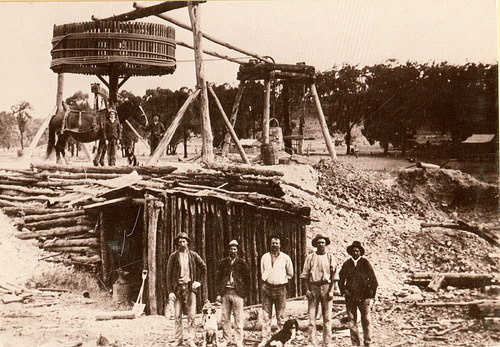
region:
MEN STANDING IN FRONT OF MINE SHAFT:
[158, 220, 390, 345]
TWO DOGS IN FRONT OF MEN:
[191, 304, 317, 342]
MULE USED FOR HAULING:
[47, 94, 154, 162]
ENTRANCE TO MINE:
[78, 170, 326, 314]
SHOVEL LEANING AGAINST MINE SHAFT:
[126, 265, 163, 319]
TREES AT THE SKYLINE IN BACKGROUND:
[140, 59, 493, 156]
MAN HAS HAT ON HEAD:
[165, 228, 204, 257]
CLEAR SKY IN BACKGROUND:
[6, 0, 492, 78]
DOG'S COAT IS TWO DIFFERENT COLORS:
[265, 313, 311, 345]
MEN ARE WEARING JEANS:
[163, 281, 389, 344]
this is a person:
[338, 240, 386, 341]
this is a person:
[295, 223, 354, 342]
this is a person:
[256, 231, 301, 333]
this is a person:
[206, 216, 251, 344]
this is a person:
[146, 227, 206, 344]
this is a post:
[190, 7, 217, 163]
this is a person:
[136, 107, 176, 158]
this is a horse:
[29, 90, 151, 191]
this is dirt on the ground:
[401, 273, 491, 327]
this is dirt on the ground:
[306, 182, 406, 237]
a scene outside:
[9, 6, 491, 344]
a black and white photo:
[6, 5, 491, 338]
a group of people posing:
[138, 211, 388, 342]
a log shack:
[68, 160, 325, 327]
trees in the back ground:
[5, 31, 496, 154]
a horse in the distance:
[42, 86, 152, 171]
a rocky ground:
[309, 151, 499, 345]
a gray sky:
[3, 2, 498, 126]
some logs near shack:
[2, 159, 252, 271]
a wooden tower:
[33, 2, 361, 167]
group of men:
[164, 231, 380, 345]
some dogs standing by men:
[199, 296, 299, 345]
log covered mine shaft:
[0, 162, 312, 315]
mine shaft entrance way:
[100, 197, 150, 314]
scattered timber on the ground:
[404, 217, 499, 344]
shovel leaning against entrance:
[131, 267, 149, 317]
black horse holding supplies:
[46, 95, 150, 164]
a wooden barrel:
[259, 140, 281, 164]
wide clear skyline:
[0, 1, 499, 123]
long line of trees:
[0, 56, 499, 153]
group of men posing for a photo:
[165, 230, 379, 345]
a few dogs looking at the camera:
[200, 300, 300, 345]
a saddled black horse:
[45, 92, 148, 166]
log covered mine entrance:
[0, 161, 312, 317]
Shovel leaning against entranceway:
[131, 267, 148, 316]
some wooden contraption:
[18, 0, 340, 163]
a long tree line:
[1, 55, 498, 151]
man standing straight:
[101, 107, 122, 167]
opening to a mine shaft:
[97, 199, 147, 301]